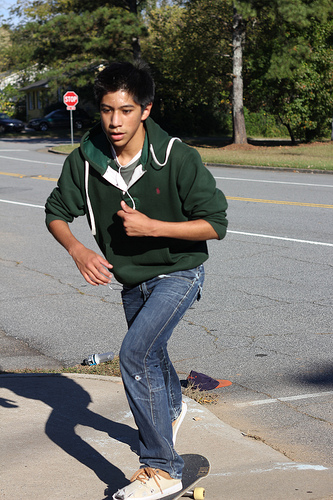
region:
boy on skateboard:
[45, 60, 224, 497]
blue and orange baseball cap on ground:
[185, 367, 231, 390]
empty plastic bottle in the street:
[81, 350, 114, 366]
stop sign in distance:
[62, 90, 78, 143]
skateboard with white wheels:
[104, 454, 211, 497]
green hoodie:
[43, 117, 226, 287]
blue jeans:
[114, 263, 205, 478]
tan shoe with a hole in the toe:
[112, 466, 184, 497]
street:
[1, 142, 330, 458]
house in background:
[18, 75, 67, 122]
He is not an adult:
[77, 52, 206, 172]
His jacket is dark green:
[42, 123, 273, 324]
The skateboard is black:
[73, 398, 239, 498]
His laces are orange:
[121, 438, 195, 494]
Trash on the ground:
[36, 319, 153, 376]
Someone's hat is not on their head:
[178, 349, 249, 398]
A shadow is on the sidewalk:
[5, 339, 216, 497]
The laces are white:
[66, 149, 119, 241]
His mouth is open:
[102, 121, 145, 149]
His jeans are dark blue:
[99, 267, 236, 475]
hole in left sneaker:
[109, 488, 143, 498]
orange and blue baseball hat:
[180, 363, 246, 402]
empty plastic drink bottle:
[75, 346, 123, 369]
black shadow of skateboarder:
[3, 367, 128, 494]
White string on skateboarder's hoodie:
[149, 138, 192, 163]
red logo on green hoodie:
[150, 186, 173, 203]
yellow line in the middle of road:
[268, 194, 326, 226]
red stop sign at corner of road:
[57, 87, 91, 114]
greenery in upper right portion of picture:
[267, 24, 323, 94]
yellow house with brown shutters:
[4, 73, 75, 121]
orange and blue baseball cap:
[178, 364, 240, 397]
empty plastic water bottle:
[78, 344, 122, 372]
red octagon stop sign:
[54, 73, 83, 119]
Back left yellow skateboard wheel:
[190, 484, 219, 498]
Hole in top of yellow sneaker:
[112, 486, 134, 498]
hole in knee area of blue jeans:
[118, 367, 166, 402]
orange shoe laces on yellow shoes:
[133, 467, 174, 487]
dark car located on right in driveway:
[31, 98, 92, 139]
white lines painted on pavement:
[262, 386, 331, 413]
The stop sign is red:
[51, 76, 83, 142]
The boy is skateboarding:
[42, 60, 264, 498]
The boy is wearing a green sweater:
[30, 54, 249, 295]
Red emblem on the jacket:
[150, 182, 162, 198]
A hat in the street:
[176, 359, 244, 397]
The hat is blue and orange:
[180, 357, 238, 396]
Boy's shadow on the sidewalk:
[1, 321, 175, 499]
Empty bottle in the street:
[79, 346, 118, 365]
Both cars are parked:
[0, 97, 91, 143]